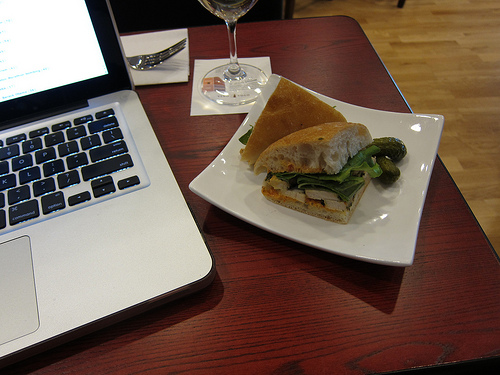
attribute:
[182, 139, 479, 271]
floor — wooden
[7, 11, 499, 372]
desk — wood grain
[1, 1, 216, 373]
laptop — silver 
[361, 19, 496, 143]
floor — wood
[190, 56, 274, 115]
paper — white 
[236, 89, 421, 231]
sandwich — cut in half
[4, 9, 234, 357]
computer — lap top, white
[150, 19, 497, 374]
wood — dark , cherry 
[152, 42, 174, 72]
napkin — white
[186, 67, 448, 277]
plate — white, square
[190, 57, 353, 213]
napkin — white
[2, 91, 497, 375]
table — wooden 